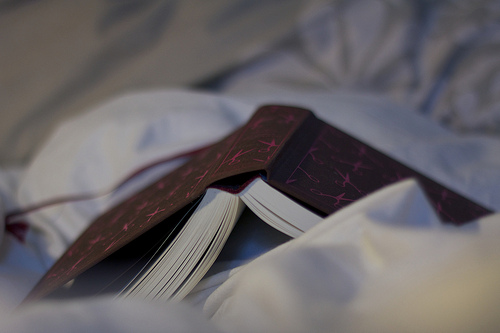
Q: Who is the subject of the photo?
A: The book.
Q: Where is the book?
A: On the blanket.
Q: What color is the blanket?
A: White.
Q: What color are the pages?
A: Cream.